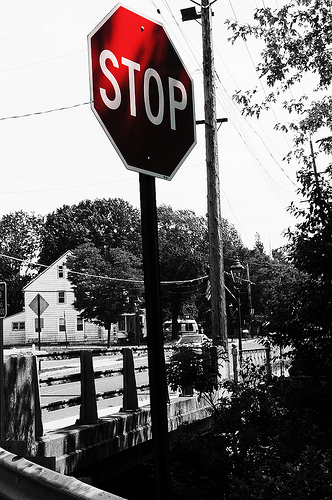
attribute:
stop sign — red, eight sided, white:
[86, 1, 197, 180]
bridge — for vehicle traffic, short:
[2, 343, 231, 473]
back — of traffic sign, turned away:
[29, 295, 50, 316]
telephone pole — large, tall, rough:
[189, 0, 228, 351]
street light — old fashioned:
[229, 254, 245, 376]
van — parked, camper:
[162, 319, 199, 340]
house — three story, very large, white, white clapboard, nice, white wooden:
[21, 249, 137, 346]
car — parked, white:
[173, 333, 213, 355]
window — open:
[58, 290, 66, 304]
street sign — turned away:
[34, 317, 43, 331]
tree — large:
[64, 243, 146, 348]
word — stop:
[99, 49, 188, 132]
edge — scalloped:
[68, 244, 139, 258]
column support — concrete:
[2, 353, 44, 440]